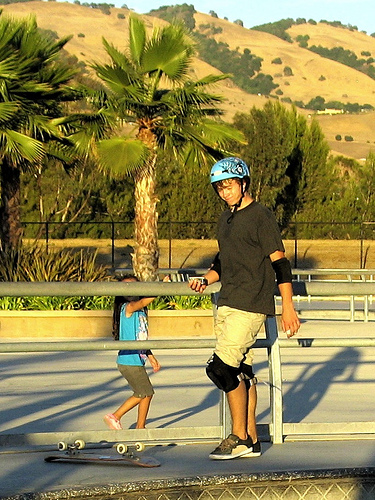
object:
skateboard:
[44, 440, 161, 468]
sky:
[55, 0, 374, 36]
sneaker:
[240, 438, 263, 457]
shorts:
[213, 304, 267, 368]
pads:
[271, 257, 294, 286]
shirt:
[116, 302, 149, 366]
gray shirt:
[210, 200, 285, 318]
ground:
[323, 115, 372, 134]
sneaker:
[103, 413, 123, 431]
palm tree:
[58, 9, 248, 283]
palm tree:
[0, 0, 85, 284]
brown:
[309, 240, 351, 269]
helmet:
[210, 157, 251, 195]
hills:
[248, 17, 373, 112]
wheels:
[117, 443, 126, 454]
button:
[139, 394, 141, 396]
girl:
[103, 273, 170, 430]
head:
[209, 157, 251, 207]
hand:
[281, 309, 301, 338]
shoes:
[208, 434, 262, 460]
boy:
[187, 156, 300, 459]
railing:
[0, 281, 375, 449]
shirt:
[210, 200, 285, 318]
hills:
[140, 0, 300, 116]